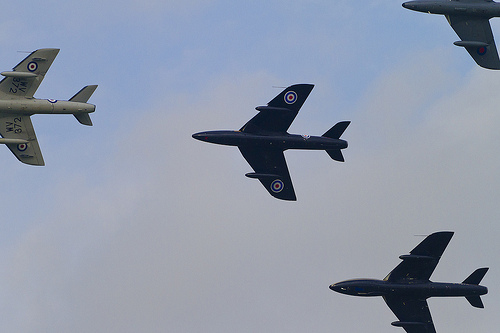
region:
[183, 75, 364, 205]
Jet flying in the middle of the others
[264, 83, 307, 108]
Bullseye on the wing of the jet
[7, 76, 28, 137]
Jet numbers under the wings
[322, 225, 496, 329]
Third jet in the group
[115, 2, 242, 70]
Blue skies during the day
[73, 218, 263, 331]
Clouds for the jets to fly through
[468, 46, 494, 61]
Red dot under the jet's wing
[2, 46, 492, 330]
Jets flying in formation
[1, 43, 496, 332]
Air show performance with jets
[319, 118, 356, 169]
Tail of the fighter jet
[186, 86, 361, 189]
the plane is black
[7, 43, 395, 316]
the planes are flying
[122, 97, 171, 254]
the sky is blue and gray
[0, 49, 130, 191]
the plane is gray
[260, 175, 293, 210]
the circle has red dot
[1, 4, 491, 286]
planes are in the sky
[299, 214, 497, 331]
the plane is black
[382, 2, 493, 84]
the plane is gray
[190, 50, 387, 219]
the plane is in the center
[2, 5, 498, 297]
four planes are in the sky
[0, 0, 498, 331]
four jets in the sky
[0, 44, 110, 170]
one jet is brown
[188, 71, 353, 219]
the jet in the middle is black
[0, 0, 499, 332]
the sky is blue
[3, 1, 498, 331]
the sky is hazy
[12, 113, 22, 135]
one jet has the number 372 on its wing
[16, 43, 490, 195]
jets have bullseyes on wings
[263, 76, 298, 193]
stickers on wings are red white and blue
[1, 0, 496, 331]
jets are in formation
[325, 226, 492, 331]
the black jet in the bottom left corner does not have stickers on either wings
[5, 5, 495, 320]
Jet fighters flying in formation.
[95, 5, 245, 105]
The sky is cloudy.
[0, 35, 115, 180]
A grey jet.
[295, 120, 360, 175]
The tail of the jet fighter.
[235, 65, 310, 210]
The jet fighter's wings.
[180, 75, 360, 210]
The jet fighter's wings are swept back.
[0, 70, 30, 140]
Writing is under the wings.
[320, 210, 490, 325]
The fighter jet has two fuel tanks.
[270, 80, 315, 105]
A bullseye symbol.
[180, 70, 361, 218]
The jet is dark blue.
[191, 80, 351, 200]
a dark blue plane in the sky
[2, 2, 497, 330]
the sky is slightly cloudy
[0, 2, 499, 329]
the sky has planes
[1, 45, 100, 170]
the back portion of a plane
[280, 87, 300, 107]
a target is painted on the plane's wing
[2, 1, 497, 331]
the planes are flying in formation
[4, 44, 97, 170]
a light colored plane is in front of the other planes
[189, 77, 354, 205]
the plane is in the middle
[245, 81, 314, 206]
the plane has wings